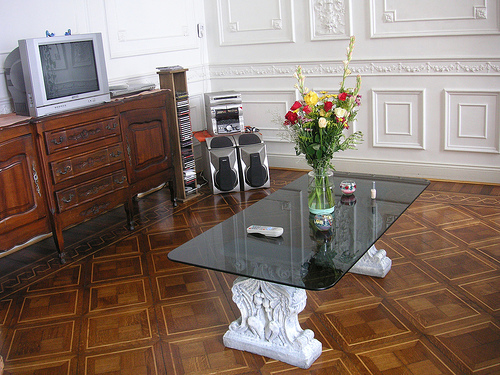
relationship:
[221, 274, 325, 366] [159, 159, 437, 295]
leg of table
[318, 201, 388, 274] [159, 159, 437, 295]
leg of table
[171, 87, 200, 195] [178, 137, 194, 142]
stack of cds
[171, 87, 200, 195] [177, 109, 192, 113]
stack of cds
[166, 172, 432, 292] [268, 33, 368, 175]
glass of flowers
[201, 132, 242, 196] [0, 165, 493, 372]
speaker on floor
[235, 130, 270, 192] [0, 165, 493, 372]
speaker on floor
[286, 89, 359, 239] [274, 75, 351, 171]
jar of flowers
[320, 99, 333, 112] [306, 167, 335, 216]
rose in glass vase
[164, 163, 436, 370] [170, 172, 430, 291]
table has glass top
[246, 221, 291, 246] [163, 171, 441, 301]
remote on top of table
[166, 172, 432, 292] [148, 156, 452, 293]
glass on top of table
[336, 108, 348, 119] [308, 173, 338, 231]
flowers in vase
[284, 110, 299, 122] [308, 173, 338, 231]
flowers in vase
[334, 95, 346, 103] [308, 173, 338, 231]
flowers in vase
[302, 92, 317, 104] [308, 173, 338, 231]
flowers in vase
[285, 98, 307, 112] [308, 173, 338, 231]
flowers in vase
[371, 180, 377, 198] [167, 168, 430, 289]
nail polish on table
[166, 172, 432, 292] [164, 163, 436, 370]
glass on table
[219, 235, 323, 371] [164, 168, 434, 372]
leg of table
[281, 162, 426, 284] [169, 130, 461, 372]
glass of table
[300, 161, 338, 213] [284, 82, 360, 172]
glass vase filled with flowers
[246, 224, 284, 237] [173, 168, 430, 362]
remote on table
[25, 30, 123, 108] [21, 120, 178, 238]
tv on cabinet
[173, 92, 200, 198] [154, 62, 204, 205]
cds inside shelf